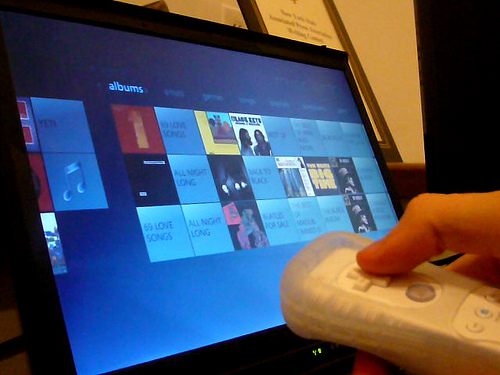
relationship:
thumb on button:
[366, 163, 493, 308] [318, 247, 465, 338]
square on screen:
[327, 156, 365, 193] [5, 19, 417, 375]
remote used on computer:
[263, 207, 494, 369] [4, 2, 383, 247]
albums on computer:
[93, 93, 402, 246] [6, 6, 452, 345]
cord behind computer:
[2, 329, 27, 354] [3, 6, 343, 366]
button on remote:
[471, 295, 492, 327] [297, 224, 499, 356]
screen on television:
[3, 10, 401, 375] [3, 4, 428, 364]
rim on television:
[52, 11, 357, 33] [3, 4, 428, 364]